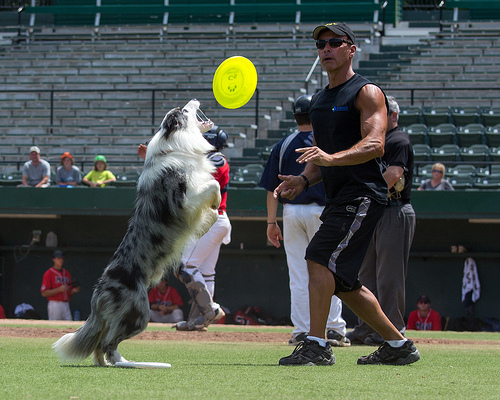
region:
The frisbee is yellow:
[206, 52, 263, 111]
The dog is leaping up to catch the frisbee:
[58, 51, 260, 369]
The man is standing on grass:
[276, 19, 416, 369]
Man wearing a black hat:
[311, 24, 361, 74]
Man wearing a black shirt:
[296, 19, 387, 201]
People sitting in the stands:
[16, 139, 120, 193]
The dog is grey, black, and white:
[50, 87, 224, 369]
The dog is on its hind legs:
[58, 88, 228, 368]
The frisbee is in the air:
[204, 47, 261, 110]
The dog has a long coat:
[50, 98, 240, 366]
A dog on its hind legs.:
[53, 94, 223, 372]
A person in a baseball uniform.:
[37, 243, 84, 323]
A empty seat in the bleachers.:
[460, 120, 487, 137]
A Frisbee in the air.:
[207, 52, 259, 112]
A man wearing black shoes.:
[271, 19, 420, 368]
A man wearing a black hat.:
[270, 20, 421, 367]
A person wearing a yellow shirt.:
[80, 149, 118, 189]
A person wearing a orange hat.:
[52, 148, 84, 186]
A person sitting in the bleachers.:
[418, 160, 456, 192]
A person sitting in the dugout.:
[404, 294, 445, 330]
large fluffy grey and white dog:
[52, 98, 221, 368]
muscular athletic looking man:
[272, 23, 419, 365]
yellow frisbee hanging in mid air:
[211, 55, 257, 108]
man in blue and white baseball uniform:
[258, 95, 349, 346]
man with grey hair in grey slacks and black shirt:
[347, 95, 416, 343]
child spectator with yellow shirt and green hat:
[82, 155, 115, 185]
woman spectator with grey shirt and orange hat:
[53, 152, 80, 186]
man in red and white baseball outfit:
[40, 251, 80, 319]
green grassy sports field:
[0, 318, 498, 398]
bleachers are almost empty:
[0, 0, 499, 192]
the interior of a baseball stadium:
[0, 0, 499, 399]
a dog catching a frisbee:
[49, 97, 221, 366]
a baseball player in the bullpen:
[40, 248, 78, 320]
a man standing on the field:
[272, 20, 419, 365]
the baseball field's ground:
[0, 318, 498, 399]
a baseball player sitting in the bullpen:
[406, 293, 441, 331]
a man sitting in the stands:
[15, 145, 50, 187]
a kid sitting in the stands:
[82, 154, 117, 188]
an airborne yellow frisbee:
[211, 55, 257, 109]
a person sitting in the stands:
[417, 162, 454, 191]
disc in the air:
[197, 52, 272, 116]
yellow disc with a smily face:
[194, 54, 269, 119]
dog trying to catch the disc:
[44, 60, 264, 363]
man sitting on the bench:
[399, 285, 443, 352]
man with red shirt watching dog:
[25, 241, 72, 325]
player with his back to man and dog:
[271, 95, 324, 324]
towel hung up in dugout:
[447, 251, 488, 313]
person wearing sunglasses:
[299, 28, 347, 54]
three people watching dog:
[4, 147, 119, 194]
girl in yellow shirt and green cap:
[81, 138, 113, 201]